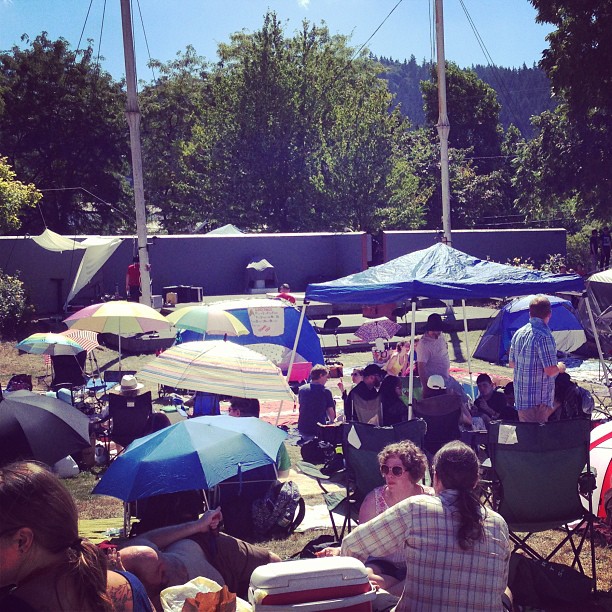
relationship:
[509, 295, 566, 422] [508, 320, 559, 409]
man wearing shirt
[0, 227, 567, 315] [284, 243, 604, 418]
blue fence behind canopy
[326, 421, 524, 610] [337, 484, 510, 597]
man in plaid shirt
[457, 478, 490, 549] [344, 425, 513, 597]
ponytail on man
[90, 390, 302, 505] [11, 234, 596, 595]
blue umbrella in park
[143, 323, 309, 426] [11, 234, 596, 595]
striped umbrella in park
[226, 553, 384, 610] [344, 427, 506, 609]
cooler next to man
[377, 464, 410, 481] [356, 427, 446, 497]
black sunglasses on woman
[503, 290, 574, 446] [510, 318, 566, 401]
man in plaid shirt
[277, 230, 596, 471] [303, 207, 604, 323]
people sitting under tent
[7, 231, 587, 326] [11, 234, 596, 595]
blue fence at park